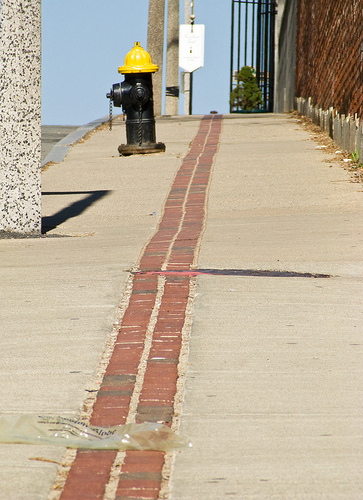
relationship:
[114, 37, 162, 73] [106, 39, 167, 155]
top on hydrant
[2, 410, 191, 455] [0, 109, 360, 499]
paper on sidewalk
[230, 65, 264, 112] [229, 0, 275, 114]
green bush front fence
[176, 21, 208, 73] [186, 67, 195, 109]
sign on pole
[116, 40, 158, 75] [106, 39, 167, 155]
top on hydrant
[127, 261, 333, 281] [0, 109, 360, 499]
manhole cover on sidewalk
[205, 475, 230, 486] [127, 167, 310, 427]
gum on sidewalk